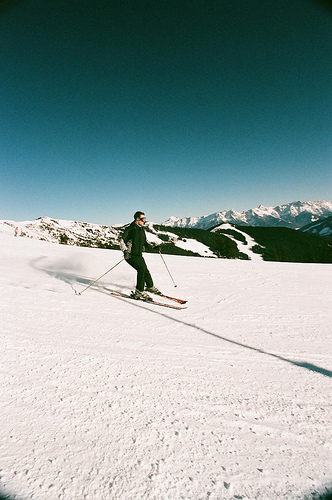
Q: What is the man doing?
A: Skiing.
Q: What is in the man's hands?
A: Ski poles.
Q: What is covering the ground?
A: White snow.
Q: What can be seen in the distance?
A: Snow covered mountains.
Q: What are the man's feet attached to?
A: Skis.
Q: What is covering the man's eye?
A: Ski goggles.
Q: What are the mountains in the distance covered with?
A: White snow.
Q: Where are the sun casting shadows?
A: On the snow.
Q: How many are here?
A: 1.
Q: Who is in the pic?
A: A man.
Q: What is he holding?
A: Stick.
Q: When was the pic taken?
A: During the day.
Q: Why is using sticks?
A: For support.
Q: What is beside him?
A: A shadow.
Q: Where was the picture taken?
A: On a slope.